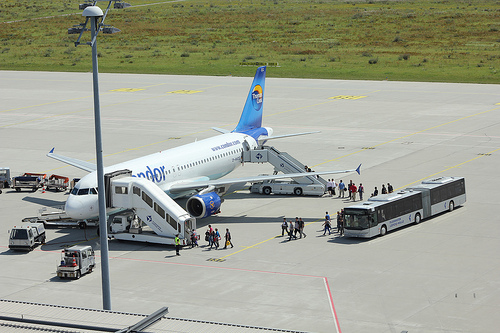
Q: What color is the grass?
A: Green.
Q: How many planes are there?
A: One.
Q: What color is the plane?
A: Blue and white.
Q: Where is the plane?
A: On the cement.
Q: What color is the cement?
A: Gray.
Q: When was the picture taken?
A: Daytime.